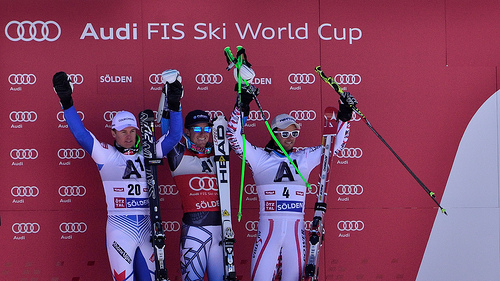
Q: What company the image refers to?
A: Audi.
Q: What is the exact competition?
A: AUDI FIS SKI World Cup.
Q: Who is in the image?
A: Achievers.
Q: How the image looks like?
A: Proud.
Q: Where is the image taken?
A: In the AUDI function.